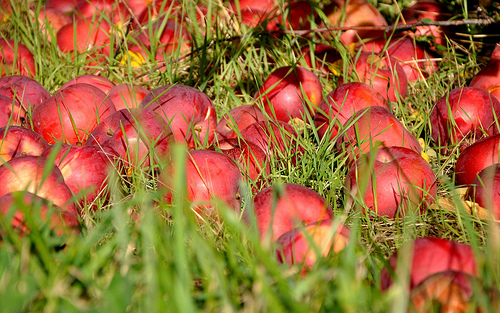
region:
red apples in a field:
[342, 139, 447, 237]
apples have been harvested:
[338, 148, 444, 219]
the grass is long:
[5, 225, 413, 311]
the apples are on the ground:
[332, 140, 443, 220]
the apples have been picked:
[346, 147, 457, 214]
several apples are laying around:
[325, 130, 454, 227]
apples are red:
[345, 140, 441, 222]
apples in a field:
[346, 146, 441, 226]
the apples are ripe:
[350, 140, 451, 228]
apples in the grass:
[5, 2, 499, 312]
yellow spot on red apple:
[303, 219, 350, 261]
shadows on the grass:
[165, 24, 499, 85]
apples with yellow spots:
[117, 36, 351, 106]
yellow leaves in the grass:
[418, 132, 487, 227]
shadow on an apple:
[270, 60, 301, 82]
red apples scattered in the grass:
[7, 16, 497, 311]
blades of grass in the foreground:
[13, 145, 499, 312]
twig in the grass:
[142, 8, 487, 90]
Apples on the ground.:
[0, 1, 498, 311]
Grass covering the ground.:
[0, 1, 498, 310]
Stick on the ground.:
[150, 10, 499, 77]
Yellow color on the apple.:
[305, 223, 348, 263]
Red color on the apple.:
[454, 130, 499, 181]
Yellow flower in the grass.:
[110, 18, 143, 75]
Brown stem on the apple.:
[189, 120, 204, 137]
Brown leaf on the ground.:
[426, 171, 494, 226]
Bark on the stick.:
[430, 16, 487, 28]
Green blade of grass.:
[160, 138, 207, 311]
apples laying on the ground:
[2, 3, 474, 309]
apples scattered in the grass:
[8, 3, 493, 309]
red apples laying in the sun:
[4, 6, 497, 303]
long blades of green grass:
[13, 6, 489, 310]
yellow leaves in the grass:
[110, 39, 490, 226]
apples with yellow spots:
[294, 214, 467, 309]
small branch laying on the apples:
[128, 2, 496, 62]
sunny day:
[2, 2, 496, 312]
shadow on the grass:
[169, 2, 341, 109]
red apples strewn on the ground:
[3, 3, 496, 310]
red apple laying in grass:
[23, 86, 119, 146]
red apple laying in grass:
[38, 137, 133, 212]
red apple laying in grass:
[1, 161, 66, 195]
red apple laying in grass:
[2, 71, 44, 106]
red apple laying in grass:
[165, 151, 242, 231]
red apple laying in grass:
[153, 81, 215, 157]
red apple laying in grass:
[252, 181, 320, 238]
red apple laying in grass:
[356, 149, 423, 205]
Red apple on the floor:
[240, 181, 331, 242]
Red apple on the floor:
[341, 138, 440, 215]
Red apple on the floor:
[334, 105, 419, 160]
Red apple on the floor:
[81, 109, 174, 174]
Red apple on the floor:
[37, 138, 109, 216]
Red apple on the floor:
[140, 79, 220, 146]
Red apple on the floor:
[338, 45, 407, 110]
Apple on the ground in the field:
[341, 139, 446, 213]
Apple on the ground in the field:
[376, 233, 477, 290]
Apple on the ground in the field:
[163, 148, 237, 207]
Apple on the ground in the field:
[143, 80, 218, 146]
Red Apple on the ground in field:
[168, 142, 242, 218]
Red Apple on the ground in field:
[347, 45, 404, 103]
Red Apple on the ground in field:
[52, 10, 112, 60]